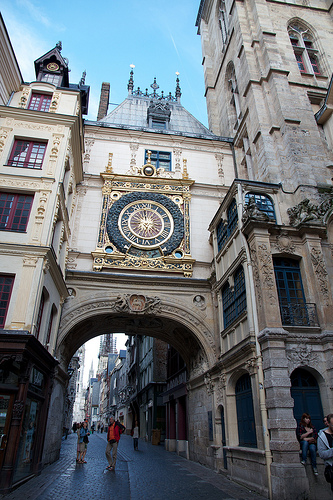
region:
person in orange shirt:
[104, 415, 123, 448]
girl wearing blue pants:
[298, 433, 318, 466]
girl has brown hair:
[300, 409, 317, 426]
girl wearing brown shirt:
[297, 422, 317, 445]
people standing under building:
[58, 403, 147, 474]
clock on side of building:
[101, 189, 200, 276]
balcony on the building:
[264, 295, 329, 332]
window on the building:
[269, 253, 318, 327]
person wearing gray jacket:
[314, 426, 332, 455]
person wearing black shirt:
[322, 428, 331, 463]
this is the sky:
[88, 19, 185, 55]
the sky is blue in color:
[118, 21, 192, 57]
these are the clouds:
[13, 28, 40, 55]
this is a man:
[104, 413, 123, 462]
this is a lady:
[298, 417, 318, 477]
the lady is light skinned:
[300, 431, 309, 436]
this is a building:
[57, 118, 326, 234]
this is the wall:
[185, 154, 211, 228]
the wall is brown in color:
[189, 158, 227, 187]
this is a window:
[230, 375, 251, 435]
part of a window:
[236, 412, 253, 455]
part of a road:
[141, 458, 159, 490]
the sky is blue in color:
[119, 3, 168, 52]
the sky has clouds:
[11, 6, 41, 51]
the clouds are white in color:
[13, 26, 41, 48]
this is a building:
[19, 13, 332, 495]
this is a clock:
[102, 170, 189, 264]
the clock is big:
[99, 155, 191, 269]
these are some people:
[68, 407, 127, 475]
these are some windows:
[9, 121, 47, 230]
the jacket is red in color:
[106, 425, 115, 437]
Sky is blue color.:
[87, 13, 181, 49]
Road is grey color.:
[53, 459, 176, 488]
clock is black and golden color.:
[93, 179, 184, 259]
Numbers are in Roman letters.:
[108, 197, 176, 263]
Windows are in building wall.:
[14, 94, 45, 280]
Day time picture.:
[27, 24, 315, 262]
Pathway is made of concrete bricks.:
[52, 467, 177, 495]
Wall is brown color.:
[22, 130, 307, 332]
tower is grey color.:
[122, 60, 190, 109]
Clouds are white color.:
[9, 25, 39, 75]